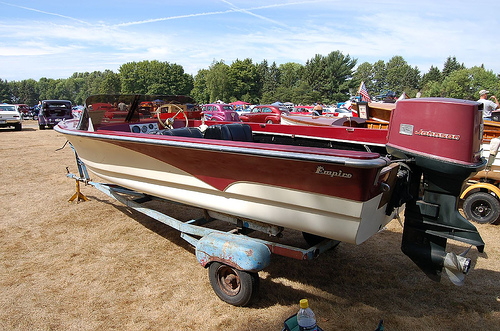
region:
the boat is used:
[5, 105, 495, 298]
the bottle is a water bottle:
[287, 296, 330, 328]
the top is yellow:
[292, 292, 312, 309]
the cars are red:
[238, 99, 285, 126]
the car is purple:
[208, 101, 246, 128]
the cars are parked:
[221, 88, 334, 115]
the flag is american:
[349, 83, 381, 106]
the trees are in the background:
[86, 58, 474, 93]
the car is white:
[7, 103, 34, 137]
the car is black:
[34, 96, 83, 139]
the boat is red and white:
[62, 125, 413, 286]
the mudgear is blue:
[191, 226, 258, 268]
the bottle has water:
[286, 294, 332, 329]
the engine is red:
[386, 94, 495, 189]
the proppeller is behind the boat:
[418, 193, 480, 285]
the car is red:
[242, 95, 282, 121]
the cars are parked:
[215, 92, 270, 113]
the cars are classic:
[222, 92, 312, 123]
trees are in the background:
[148, 67, 360, 96]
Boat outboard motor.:
[391, 94, 485, 284]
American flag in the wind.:
[357, 81, 369, 98]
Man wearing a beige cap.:
[475, 87, 492, 112]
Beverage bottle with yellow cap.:
[295, 296, 319, 328]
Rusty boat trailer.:
[115, 199, 303, 304]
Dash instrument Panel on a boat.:
[127, 120, 158, 135]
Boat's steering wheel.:
[152, 104, 192, 130]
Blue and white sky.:
[132, 2, 436, 52]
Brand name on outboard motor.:
[400, 121, 462, 142]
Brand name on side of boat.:
[315, 162, 355, 184]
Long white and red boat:
[45, 90, 491, 305]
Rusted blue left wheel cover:
[192, 231, 274, 278]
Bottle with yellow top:
[289, 292, 324, 329]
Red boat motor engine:
[383, 87, 488, 286]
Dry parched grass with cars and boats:
[0, 119, 497, 329]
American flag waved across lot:
[355, 76, 373, 104]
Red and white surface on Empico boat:
[57, 112, 417, 240]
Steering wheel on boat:
[153, 103, 193, 133]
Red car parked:
[236, 103, 291, 125]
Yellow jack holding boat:
[67, 179, 94, 202]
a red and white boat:
[43, 89, 488, 308]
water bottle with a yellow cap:
[293, 297, 322, 329]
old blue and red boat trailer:
[53, 135, 343, 306]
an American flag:
[351, 78, 374, 105]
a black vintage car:
[34, 97, 76, 129]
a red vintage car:
[238, 102, 288, 124]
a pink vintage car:
[199, 101, 244, 121]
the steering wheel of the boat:
[154, 100, 189, 128]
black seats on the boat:
[151, 119, 253, 143]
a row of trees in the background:
[0, 45, 499, 110]